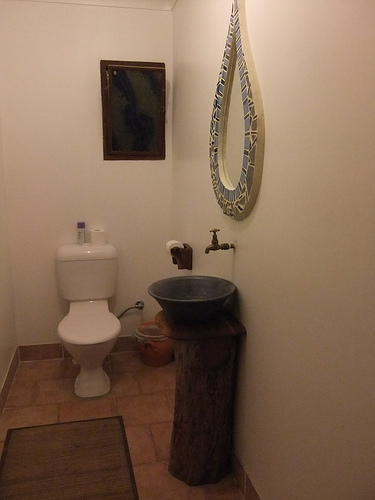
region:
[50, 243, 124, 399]
white toilet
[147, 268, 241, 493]
toilet sink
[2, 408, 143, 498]
part of a brown toilet floor mat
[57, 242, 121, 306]
white toilet tank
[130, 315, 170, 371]
orange trash can with a plastic bag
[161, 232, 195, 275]
white toilet paper with a wall holder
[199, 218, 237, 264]
toilet foucet for the sink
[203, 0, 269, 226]
decorated mirror mounted on a restroom wall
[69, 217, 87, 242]
air freshner can on top of a toilet tank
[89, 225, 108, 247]
white toilet paper on top of a toilet tank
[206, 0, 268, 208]
mosaic piece of art on wall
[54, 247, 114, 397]
a white ceramic toilet in bathroom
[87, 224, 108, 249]
extra roll of toilet paper on tank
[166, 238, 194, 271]
brown toilet paper holder with toilet paper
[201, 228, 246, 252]
brass water faucet coming out of wall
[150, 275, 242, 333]
a dark bowl used as a sink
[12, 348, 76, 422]
floor covered in light brown ceramic tile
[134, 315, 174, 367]
brown pottery with white edge used as waste basket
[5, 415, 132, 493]
Bathroom throw rug with dark brown edge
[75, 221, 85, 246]
can of spray deodorant on back of toilet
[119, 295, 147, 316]
silver pipe of the toilet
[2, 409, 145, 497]
square mat on the floor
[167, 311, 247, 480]
wooden stand of the sink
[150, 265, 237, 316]
large sink bowl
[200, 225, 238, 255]
a spout coming out of the wall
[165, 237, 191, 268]
a toilet paper holder with paper on it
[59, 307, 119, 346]
a toilet lid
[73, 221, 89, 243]
an air freshener behind the toilet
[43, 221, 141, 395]
a white toilet on the wall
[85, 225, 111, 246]
extra roll of toilet paper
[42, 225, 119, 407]
a white toilet bowl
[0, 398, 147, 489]
a rug on the floor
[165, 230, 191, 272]
a roll of toilet paper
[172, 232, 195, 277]
a wood toilet paper holder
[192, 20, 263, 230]
a mirror hanging on the wall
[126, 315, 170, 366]
a flower pot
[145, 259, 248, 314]
a sink bowl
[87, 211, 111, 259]
a roll of toilet paper on a toilet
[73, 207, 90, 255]
a spray can on a toilet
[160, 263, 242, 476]
a bowl sitting on a log standing up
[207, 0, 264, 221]
the tear shaped framed mirror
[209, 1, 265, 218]
the framed mirror hanging on the wall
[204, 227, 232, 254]
the water faucet hanging above the sink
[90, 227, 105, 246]
the toilet paper roll on the toilet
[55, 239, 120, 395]
the white toilet bowl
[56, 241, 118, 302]
the white tank on the toilet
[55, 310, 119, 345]
the seat cover for the toilet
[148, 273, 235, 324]
the bathroom sink on the stand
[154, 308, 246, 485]
the stand under the bathroom sink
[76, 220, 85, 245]
the spray can on the toilet